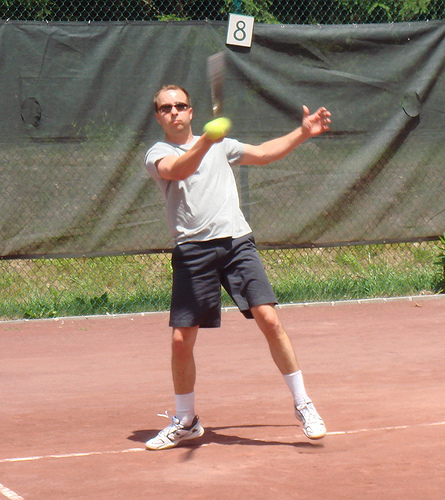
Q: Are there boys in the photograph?
A: No, there are no boys.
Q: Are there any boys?
A: No, there are no boys.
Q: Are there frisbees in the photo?
A: No, there are no frisbees.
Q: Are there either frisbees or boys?
A: No, there are no frisbees or boys.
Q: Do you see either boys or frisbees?
A: No, there are no frisbees or boys.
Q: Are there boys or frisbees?
A: No, there are no frisbees or boys.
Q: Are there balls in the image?
A: Yes, there is a ball.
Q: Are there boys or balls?
A: Yes, there is a ball.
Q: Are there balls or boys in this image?
A: Yes, there is a ball.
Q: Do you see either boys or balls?
A: Yes, there is a ball.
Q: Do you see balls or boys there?
A: Yes, there is a ball.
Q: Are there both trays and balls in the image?
A: No, there is a ball but no trays.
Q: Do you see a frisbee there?
A: No, there are no frisbees.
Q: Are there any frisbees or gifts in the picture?
A: No, there are no frisbees or gifts.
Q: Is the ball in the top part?
A: Yes, the ball is in the top of the image.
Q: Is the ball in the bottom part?
A: No, the ball is in the top of the image.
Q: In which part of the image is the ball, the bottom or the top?
A: The ball is in the top of the image.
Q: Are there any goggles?
A: Yes, there are goggles.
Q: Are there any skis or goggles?
A: Yes, there are goggles.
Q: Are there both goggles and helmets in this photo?
A: No, there are goggles but no helmets.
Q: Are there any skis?
A: No, there are no skis.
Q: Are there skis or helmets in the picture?
A: No, there are no skis or helmets.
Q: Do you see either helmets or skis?
A: No, there are no skis or helmets.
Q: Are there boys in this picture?
A: No, there are no boys.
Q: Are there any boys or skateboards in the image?
A: No, there are no boys or skateboards.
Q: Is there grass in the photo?
A: Yes, there is grass.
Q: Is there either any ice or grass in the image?
A: Yes, there is grass.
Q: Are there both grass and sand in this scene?
A: No, there is grass but no sand.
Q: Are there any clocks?
A: No, there are no clocks.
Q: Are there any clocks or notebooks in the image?
A: No, there are no clocks or notebooks.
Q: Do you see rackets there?
A: Yes, there is a racket.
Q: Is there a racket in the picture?
A: Yes, there is a racket.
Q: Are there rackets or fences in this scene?
A: Yes, there is a racket.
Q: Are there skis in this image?
A: No, there are no skis.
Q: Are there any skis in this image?
A: No, there are no skis.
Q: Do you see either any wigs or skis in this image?
A: No, there are no skis or wigs.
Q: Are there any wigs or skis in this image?
A: No, there are no skis or wigs.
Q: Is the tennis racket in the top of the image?
A: Yes, the tennis racket is in the top of the image.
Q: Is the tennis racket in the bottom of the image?
A: No, the tennis racket is in the top of the image.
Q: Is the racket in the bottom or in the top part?
A: The racket is in the top of the image.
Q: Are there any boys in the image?
A: No, there are no boys.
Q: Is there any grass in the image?
A: Yes, there is grass.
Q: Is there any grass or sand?
A: Yes, there is grass.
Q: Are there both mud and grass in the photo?
A: No, there is grass but no mud.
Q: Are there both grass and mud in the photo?
A: No, there is grass but no mud.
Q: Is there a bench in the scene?
A: No, there are no benches.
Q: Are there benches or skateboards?
A: No, there are no benches or skateboards.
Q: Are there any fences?
A: Yes, there is a fence.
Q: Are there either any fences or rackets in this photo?
A: Yes, there is a fence.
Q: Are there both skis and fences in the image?
A: No, there is a fence but no skis.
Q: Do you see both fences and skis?
A: No, there is a fence but no skis.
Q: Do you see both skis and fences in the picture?
A: No, there is a fence but no skis.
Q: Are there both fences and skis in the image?
A: No, there is a fence but no skis.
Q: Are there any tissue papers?
A: No, there are no tissue papers.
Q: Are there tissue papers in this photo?
A: No, there are no tissue papers.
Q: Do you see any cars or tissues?
A: No, there are no tissues or cars.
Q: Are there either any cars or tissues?
A: No, there are no tissues or cars.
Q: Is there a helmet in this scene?
A: No, there are no helmets.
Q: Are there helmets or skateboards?
A: No, there are no helmets or skateboards.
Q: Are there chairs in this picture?
A: No, there are no chairs.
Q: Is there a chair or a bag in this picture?
A: No, there are no chairs or bags.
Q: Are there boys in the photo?
A: No, there are no boys.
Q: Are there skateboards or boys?
A: No, there are no boys or skateboards.